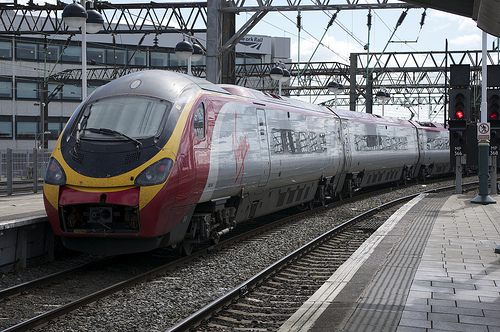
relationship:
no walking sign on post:
[474, 115, 492, 154] [460, 35, 493, 235]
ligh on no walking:
[440, 67, 468, 130] [477, 122, 491, 141]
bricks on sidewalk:
[436, 264, 481, 320] [440, 200, 469, 249]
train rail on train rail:
[0, 247, 202, 331] [124, 225, 233, 288]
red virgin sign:
[225, 117, 252, 148] [203, 115, 261, 206]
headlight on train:
[7, 153, 175, 184] [41, 74, 248, 250]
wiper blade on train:
[38, 101, 154, 163] [41, 74, 248, 250]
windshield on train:
[51, 72, 204, 156] [41, 74, 248, 250]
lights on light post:
[57, 1, 99, 32] [55, 0, 99, 116]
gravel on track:
[124, 275, 176, 317] [171, 180, 499, 332]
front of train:
[55, 53, 215, 217] [41, 74, 248, 250]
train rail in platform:
[0, 247, 202, 331] [0, 188, 500, 332]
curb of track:
[323, 248, 396, 305] [171, 180, 499, 332]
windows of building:
[253, 128, 323, 154] [11, 30, 154, 75]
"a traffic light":
[270, 42, 274, 43] [451, 84, 473, 123]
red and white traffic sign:
[225, 117, 252, 148] [474, 115, 492, 154]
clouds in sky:
[294, 26, 319, 67] [412, 19, 438, 33]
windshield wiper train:
[51, 72, 204, 156] [41, 74, 248, 250]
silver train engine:
[292, 165, 337, 178] [48, 88, 212, 182]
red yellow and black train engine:
[82, 126, 218, 220] [48, 88, 212, 182]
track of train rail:
[171, 180, 499, 332] [0, 247, 202, 331]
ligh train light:
[446, 64, 471, 133] [442, 57, 481, 165]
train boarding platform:
[41, 74, 248, 250] [414, 253, 447, 299]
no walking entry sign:
[477, 122, 491, 141] [203, 115, 261, 206]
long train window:
[291, 139, 453, 153] [262, 122, 313, 167]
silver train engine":
[292, 165, 337, 178] [1, 58, 270, 211]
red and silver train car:
[225, 117, 252, 148] [330, 118, 416, 192]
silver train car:
[292, 165, 337, 178] [330, 118, 416, 192]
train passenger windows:
[41, 74, 248, 250] [253, 128, 323, 154]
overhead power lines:
[262, 17, 352, 63] [321, 29, 413, 54]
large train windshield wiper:
[41, 74, 248, 250] [67, 106, 165, 155]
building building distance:
[0, 4, 291, 182] [300, 29, 321, 44]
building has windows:
[11, 30, 154, 75] [253, 128, 323, 154]